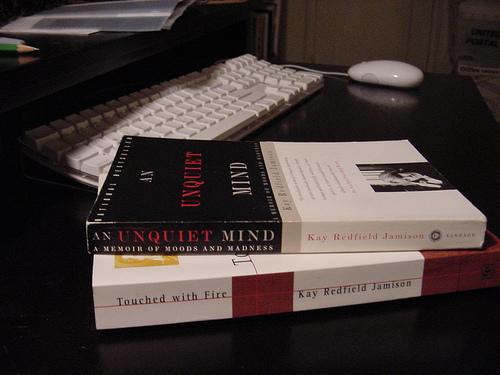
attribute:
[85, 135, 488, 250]
book — paperback, stacked, black white, grey, white andred, red, black, soft cover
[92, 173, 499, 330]
book — paperback, stacked, red, white, soft cover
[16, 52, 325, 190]
keyboard — white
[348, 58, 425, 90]
mouse — connected, white, shiny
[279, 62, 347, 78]
wire — grey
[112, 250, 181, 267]
mark — yellow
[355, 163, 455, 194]
photo — black, white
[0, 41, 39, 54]
pencil — green, wooden, pointed, reflecting, sharpened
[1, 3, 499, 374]
desk — shiny, brown, dark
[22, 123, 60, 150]
button — white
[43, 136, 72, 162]
button — white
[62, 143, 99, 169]
button — white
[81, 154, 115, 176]
button — white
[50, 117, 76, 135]
button — white